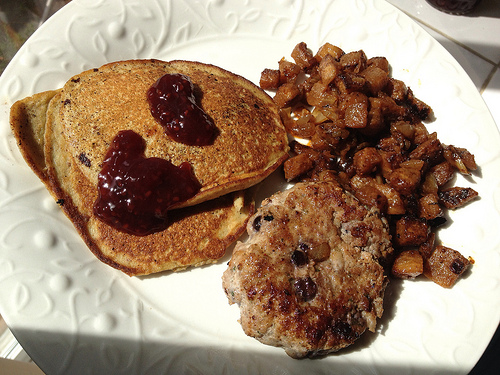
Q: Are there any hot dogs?
A: No, there are no hot dogs.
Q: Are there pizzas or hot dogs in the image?
A: No, there are no hot dogs or pizzas.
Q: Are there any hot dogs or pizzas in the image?
A: No, there are no hot dogs or pizzas.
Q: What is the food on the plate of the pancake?
A: The food is a sausage.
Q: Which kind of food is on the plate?
A: The food is a sausage.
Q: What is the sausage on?
A: The sausage is on the plate.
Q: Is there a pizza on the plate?
A: No, there is a sausage on the plate.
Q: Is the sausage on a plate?
A: Yes, the sausage is on a plate.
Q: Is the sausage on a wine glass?
A: No, the sausage is on a plate.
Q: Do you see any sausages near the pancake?
A: Yes, there is a sausage near the pancake.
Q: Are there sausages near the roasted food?
A: Yes, there is a sausage near the pancake.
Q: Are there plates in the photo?
A: Yes, there is a plate.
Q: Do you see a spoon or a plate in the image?
A: Yes, there is a plate.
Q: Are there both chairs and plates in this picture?
A: No, there is a plate but no chairs.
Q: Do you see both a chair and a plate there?
A: No, there is a plate but no chairs.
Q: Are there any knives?
A: No, there are no knives.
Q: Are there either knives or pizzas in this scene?
A: No, there are no knives or pizzas.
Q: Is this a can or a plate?
A: This is a plate.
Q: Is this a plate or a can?
A: This is a plate.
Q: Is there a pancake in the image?
A: Yes, there is a pancake.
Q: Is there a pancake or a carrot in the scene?
A: Yes, there is a pancake.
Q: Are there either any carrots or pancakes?
A: Yes, there is a pancake.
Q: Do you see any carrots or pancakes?
A: Yes, there is a pancake.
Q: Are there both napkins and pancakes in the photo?
A: No, there is a pancake but no napkins.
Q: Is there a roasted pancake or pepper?
A: Yes, there is a roasted pancake.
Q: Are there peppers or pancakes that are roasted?
A: Yes, the pancake is roasted.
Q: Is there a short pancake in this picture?
A: Yes, there is a short pancake.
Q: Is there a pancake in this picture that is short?
A: Yes, there is a pancake that is short.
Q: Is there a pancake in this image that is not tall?
A: Yes, there is a short pancake.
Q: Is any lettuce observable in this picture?
A: No, there is no lettuce.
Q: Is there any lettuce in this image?
A: No, there is no lettuce.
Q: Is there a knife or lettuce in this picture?
A: No, there are no lettuce or knives.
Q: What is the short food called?
A: The food is a pancake.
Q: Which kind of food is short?
A: The food is a pancake.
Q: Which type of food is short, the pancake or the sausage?
A: The pancake is short.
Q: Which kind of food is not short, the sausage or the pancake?
A: The sausage is not short.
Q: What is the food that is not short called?
A: The food is a sausage.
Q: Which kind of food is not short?
A: The food is a sausage.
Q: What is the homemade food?
A: The food is a pancake.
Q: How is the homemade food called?
A: The food is a pancake.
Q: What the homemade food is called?
A: The food is a pancake.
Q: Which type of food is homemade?
A: The food is a pancake.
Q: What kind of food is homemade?
A: The food is a pancake.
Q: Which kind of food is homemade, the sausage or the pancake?
A: The pancake is homemade.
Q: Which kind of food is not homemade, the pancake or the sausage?
A: The sausage is not homemade.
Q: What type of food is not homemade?
A: The food is a sausage.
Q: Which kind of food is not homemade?
A: The food is a sausage.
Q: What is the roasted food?
A: The food is a pancake.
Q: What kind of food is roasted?
A: The food is a pancake.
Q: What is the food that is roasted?
A: The food is a pancake.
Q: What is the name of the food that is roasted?
A: The food is a pancake.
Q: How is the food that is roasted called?
A: The food is a pancake.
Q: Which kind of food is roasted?
A: The food is a pancake.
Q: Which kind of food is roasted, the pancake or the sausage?
A: The pancake is roasted.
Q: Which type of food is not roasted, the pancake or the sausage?
A: The sausage is not roasted.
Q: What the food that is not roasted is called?
A: The food is a sausage.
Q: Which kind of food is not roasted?
A: The food is a sausage.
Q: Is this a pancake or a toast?
A: This is a pancake.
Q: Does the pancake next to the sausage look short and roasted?
A: Yes, the pancake is short and roasted.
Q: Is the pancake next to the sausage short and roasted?
A: Yes, the pancake is short and roasted.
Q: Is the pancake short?
A: Yes, the pancake is short.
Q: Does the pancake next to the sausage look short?
A: Yes, the pancake is short.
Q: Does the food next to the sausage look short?
A: Yes, the pancake is short.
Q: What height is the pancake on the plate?
A: The pancake is short.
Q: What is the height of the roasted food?
A: The pancake is short.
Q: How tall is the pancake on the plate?
A: The pancake is short.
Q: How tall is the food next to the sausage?
A: The pancake is short.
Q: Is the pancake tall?
A: No, the pancake is short.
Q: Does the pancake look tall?
A: No, the pancake is short.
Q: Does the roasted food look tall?
A: No, the pancake is short.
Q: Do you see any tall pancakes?
A: No, there is a pancake but it is short.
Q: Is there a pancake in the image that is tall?
A: No, there is a pancake but it is short.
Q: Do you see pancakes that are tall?
A: No, there is a pancake but it is short.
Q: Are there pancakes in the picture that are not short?
A: No, there is a pancake but it is short.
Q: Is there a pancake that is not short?
A: No, there is a pancake but it is short.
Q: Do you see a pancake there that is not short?
A: No, there is a pancake but it is short.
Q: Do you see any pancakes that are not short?
A: No, there is a pancake but it is short.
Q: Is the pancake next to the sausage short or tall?
A: The pancake is short.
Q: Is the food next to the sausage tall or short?
A: The pancake is short.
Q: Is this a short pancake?
A: Yes, this is a short pancake.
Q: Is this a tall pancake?
A: No, this is a short pancake.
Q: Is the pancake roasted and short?
A: Yes, the pancake is roasted and short.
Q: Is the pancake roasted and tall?
A: No, the pancake is roasted but short.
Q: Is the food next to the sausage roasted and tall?
A: No, the pancake is roasted but short.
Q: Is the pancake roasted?
A: Yes, the pancake is roasted.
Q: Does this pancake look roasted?
A: Yes, the pancake is roasted.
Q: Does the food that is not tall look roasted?
A: Yes, the pancake is roasted.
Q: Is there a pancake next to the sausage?
A: Yes, there is a pancake next to the sausage.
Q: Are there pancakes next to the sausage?
A: Yes, there is a pancake next to the sausage.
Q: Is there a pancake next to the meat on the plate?
A: Yes, there is a pancake next to the sausage.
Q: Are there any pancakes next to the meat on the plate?
A: Yes, there is a pancake next to the sausage.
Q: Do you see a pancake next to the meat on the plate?
A: Yes, there is a pancake next to the sausage.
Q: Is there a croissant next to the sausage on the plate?
A: No, there is a pancake next to the sausage.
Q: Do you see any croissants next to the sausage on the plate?
A: No, there is a pancake next to the sausage.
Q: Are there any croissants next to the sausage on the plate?
A: No, there is a pancake next to the sausage.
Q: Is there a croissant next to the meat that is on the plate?
A: No, there is a pancake next to the sausage.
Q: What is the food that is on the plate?
A: The food is a pancake.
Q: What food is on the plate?
A: The food is a pancake.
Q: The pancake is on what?
A: The pancake is on the plate.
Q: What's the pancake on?
A: The pancake is on the plate.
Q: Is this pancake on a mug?
A: No, the pancake is on the plate.